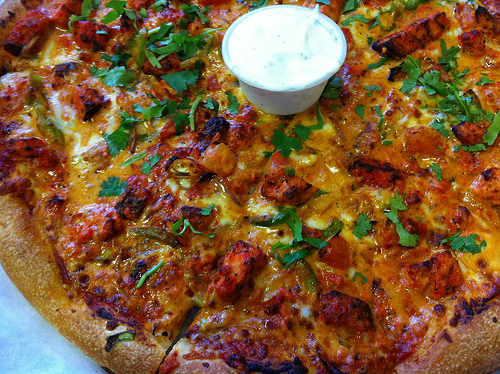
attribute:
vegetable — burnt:
[103, 319, 133, 357]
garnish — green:
[380, 189, 421, 249]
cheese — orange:
[39, 9, 499, 282]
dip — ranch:
[230, 7, 330, 84]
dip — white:
[224, 7, 336, 82]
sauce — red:
[204, 242, 275, 305]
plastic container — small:
[187, 11, 353, 119]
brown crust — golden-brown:
[6, 221, 78, 326]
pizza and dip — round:
[171, 5, 376, 149]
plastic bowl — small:
[217, 9, 354, 120]